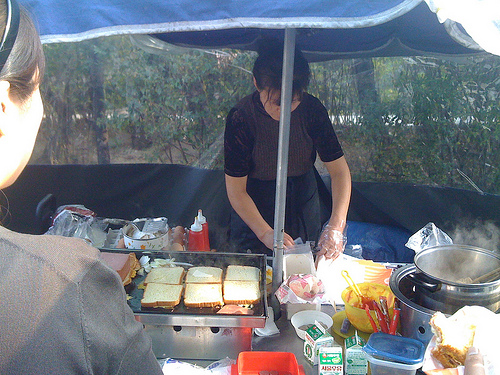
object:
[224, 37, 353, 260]
woman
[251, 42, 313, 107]
hair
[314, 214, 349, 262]
glove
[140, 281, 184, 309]
sandwich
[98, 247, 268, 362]
grill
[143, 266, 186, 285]
sandwich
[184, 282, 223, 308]
sandwich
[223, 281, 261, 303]
sandwich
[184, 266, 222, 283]
sandwich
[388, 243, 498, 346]
pot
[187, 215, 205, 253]
ketchup bottle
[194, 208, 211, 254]
ketchup bottle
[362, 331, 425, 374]
tupperware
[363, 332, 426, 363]
lid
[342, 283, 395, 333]
bowl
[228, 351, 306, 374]
container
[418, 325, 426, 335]
hole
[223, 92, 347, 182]
blouse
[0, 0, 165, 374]
woman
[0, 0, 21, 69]
hairband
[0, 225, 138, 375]
shirt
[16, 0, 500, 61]
tent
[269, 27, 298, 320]
pole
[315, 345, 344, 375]
container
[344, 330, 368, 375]
container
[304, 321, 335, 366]
container